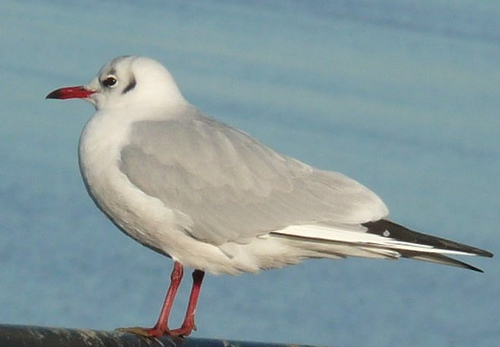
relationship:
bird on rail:
[41, 46, 470, 321] [12, 318, 136, 344]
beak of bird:
[31, 71, 88, 107] [41, 46, 470, 321]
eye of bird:
[95, 73, 122, 97] [41, 46, 470, 321]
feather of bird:
[299, 222, 407, 240] [41, 46, 470, 321]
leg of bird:
[144, 258, 178, 328] [41, 46, 470, 321]